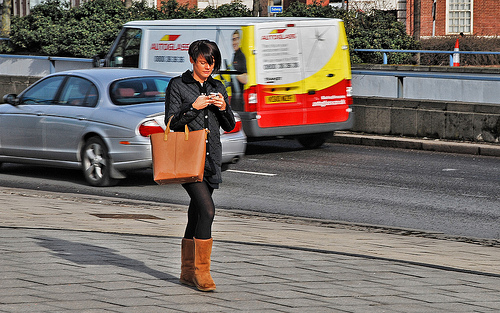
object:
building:
[402, 0, 499, 42]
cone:
[451, 36, 460, 67]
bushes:
[316, 1, 418, 66]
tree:
[7, 3, 162, 55]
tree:
[283, 2, 423, 63]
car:
[0, 67, 247, 187]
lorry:
[256, 26, 345, 121]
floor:
[229, 246, 366, 307]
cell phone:
[206, 88, 216, 103]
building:
[342, 0, 406, 32]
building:
[128, 0, 200, 17]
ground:
[201, 76, 226, 105]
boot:
[191, 237, 217, 292]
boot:
[179, 237, 195, 286]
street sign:
[266, 4, 286, 17]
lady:
[146, 40, 235, 292]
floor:
[256, 243, 273, 257]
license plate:
[265, 94, 298, 104]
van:
[94, 10, 357, 151]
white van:
[120, 18, 353, 134]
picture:
[215, 29, 252, 111]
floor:
[192, 175, 433, 311]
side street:
[1, 187, 498, 311]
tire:
[82, 136, 118, 187]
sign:
[268, 3, 283, 13]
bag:
[150, 115, 206, 185]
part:
[258, 250, 281, 285]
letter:
[271, 6, 273, 11]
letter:
[274, 7, 277, 8]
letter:
[275, 8, 276, 9]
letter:
[277, 7, 278, 10]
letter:
[279, 7, 280, 9]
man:
[222, 30, 246, 110]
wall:
[411, 2, 488, 32]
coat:
[171, 78, 193, 105]